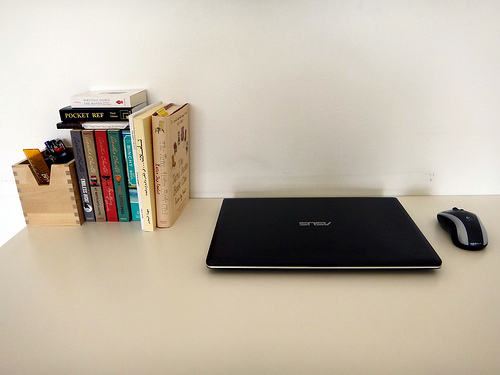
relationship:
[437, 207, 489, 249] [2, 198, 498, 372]
mouse on table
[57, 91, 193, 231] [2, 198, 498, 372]
books on table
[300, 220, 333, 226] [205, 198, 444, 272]
asus logo on laptop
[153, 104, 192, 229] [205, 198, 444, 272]
book near laptop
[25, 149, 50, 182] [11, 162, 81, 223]
ruler in desk container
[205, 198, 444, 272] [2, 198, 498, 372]
laptop on table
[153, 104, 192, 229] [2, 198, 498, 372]
book on table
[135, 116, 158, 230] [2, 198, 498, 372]
book on table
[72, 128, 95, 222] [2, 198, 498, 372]
book on table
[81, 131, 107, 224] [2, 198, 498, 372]
book on table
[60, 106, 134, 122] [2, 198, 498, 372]
book on table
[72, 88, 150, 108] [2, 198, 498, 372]
book on table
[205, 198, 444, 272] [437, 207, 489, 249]
laptop and mouse